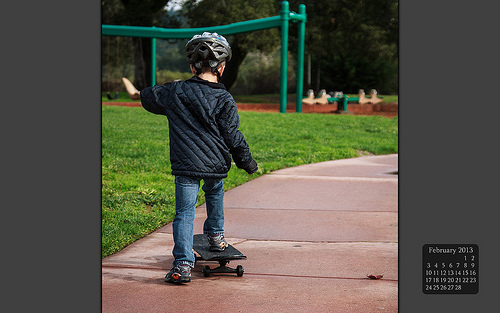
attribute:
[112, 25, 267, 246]
boy — little boy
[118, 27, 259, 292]
boy — little boy, skateboarding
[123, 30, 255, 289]
he — trying to skateboard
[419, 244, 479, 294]
calendar — very small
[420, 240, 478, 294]
calendar — February 2013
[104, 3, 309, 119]
playground — green, jungle gym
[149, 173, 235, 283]
jeans — blue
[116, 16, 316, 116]
monkey bars — green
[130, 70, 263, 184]
coat — black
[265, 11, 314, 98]
posts — green